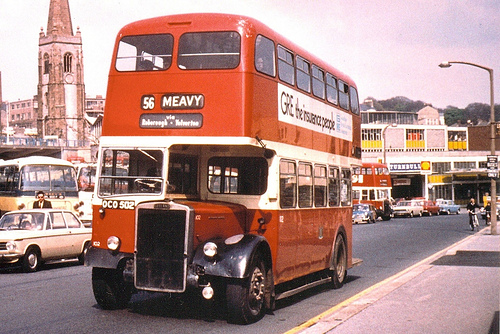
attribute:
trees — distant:
[370, 96, 492, 116]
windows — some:
[226, 32, 371, 111]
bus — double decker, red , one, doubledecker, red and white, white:
[85, 12, 365, 324]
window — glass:
[92, 136, 185, 204]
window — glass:
[265, 152, 317, 212]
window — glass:
[284, 159, 330, 199]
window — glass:
[306, 159, 338, 202]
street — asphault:
[28, 182, 461, 332]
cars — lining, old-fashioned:
[358, 196, 460, 221]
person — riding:
[455, 189, 487, 213]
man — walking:
[28, 185, 67, 217]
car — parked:
[10, 202, 118, 267]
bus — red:
[88, 22, 344, 307]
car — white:
[2, 205, 92, 274]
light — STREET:
[435, 51, 483, 223]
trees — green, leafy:
[356, 87, 497, 123]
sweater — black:
[462, 203, 482, 222]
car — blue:
[435, 185, 464, 219]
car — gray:
[0, 203, 98, 273]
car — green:
[352, 200, 384, 225]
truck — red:
[351, 157, 396, 218]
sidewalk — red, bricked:
[290, 228, 496, 331]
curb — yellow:
[283, 233, 483, 332]